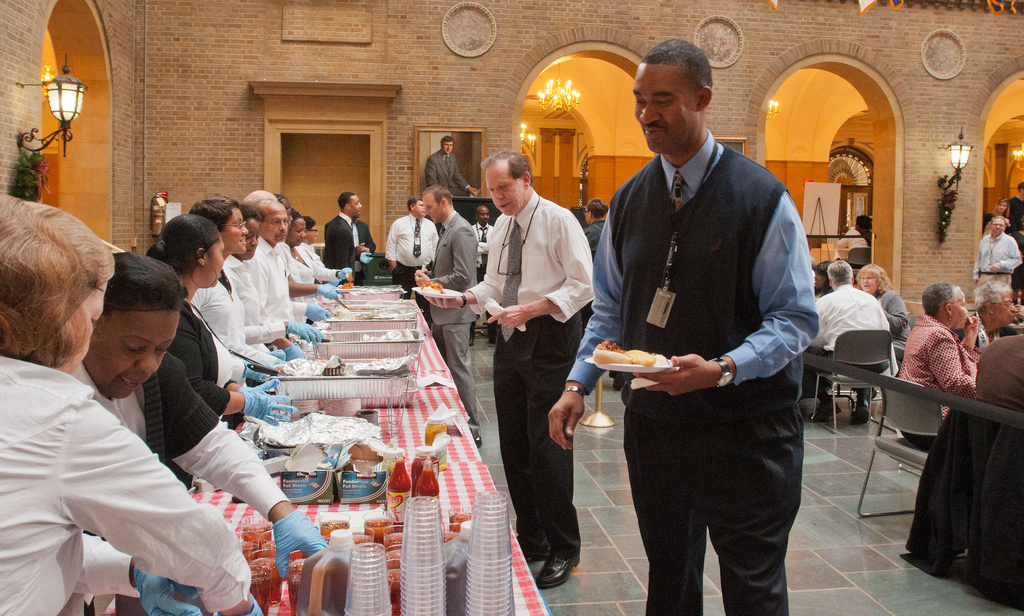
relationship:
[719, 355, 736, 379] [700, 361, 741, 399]
watch on wrist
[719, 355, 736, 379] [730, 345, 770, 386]
watch near cuff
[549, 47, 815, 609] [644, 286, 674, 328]
man wearing badge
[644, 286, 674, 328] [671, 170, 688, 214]
badge below tie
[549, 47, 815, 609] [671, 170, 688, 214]
man has tie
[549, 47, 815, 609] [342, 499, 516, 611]
man across from cups in stack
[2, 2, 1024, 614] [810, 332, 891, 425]
room shows grey chair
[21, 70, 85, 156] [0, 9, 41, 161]
light on wall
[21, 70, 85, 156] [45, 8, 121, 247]
light next to arch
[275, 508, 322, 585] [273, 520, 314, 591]
hand has blue glove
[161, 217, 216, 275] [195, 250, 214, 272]
hair net on head above ear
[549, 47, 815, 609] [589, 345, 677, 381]
man has hand with plate of food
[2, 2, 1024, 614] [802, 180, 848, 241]
room shows a picture on wall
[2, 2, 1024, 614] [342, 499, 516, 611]
room has cups in stack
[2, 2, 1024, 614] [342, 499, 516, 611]
room has clear cups in stack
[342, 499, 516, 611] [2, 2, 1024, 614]
stacked cups inside room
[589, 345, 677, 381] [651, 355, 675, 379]
plate of food shows food on plate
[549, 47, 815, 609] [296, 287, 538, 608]
man in front of table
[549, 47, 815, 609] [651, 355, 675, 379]
man holding plate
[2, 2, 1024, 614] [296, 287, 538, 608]
room shows man near table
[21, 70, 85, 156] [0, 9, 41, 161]
light attached to wall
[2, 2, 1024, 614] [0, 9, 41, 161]
room shows light  on wall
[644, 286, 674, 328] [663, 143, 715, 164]
badge on neck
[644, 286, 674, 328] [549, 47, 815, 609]
badge on man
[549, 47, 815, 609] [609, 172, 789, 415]
man in vest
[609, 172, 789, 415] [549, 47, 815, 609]
vest on man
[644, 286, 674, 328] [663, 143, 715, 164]
badge around neck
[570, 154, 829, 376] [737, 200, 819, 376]
shirt has sleeve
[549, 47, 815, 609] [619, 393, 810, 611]
man has pants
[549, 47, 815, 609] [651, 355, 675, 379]
african american has plate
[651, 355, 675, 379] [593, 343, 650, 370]
plate has food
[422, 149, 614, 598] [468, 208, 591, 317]
man has shirt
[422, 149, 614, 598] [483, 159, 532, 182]
man has hair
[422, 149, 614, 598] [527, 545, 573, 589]
man has shoes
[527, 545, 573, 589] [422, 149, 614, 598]
shoes are on man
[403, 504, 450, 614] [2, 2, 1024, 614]
cups are in stack in room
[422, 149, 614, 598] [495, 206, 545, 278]
man has glasses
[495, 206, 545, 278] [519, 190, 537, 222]
glasses are around neck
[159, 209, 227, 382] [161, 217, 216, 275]
woman has hair net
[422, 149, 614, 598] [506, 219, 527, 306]
man has tie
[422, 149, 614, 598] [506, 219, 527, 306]
man wearing tie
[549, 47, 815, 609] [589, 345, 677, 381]
man holding plate of food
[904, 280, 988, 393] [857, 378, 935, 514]
woman on chair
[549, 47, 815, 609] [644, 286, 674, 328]
man has badge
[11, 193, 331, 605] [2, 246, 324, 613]
people in line wearing shirts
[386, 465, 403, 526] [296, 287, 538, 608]
bottle on table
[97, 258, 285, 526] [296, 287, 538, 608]
woman reaches for table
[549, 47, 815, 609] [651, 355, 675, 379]
man js holding onto plate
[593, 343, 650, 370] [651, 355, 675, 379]
food on top of plate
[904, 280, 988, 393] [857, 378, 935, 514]
woman upon chair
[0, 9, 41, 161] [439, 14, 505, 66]
wall shows decoration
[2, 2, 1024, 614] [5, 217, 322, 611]
room shows women